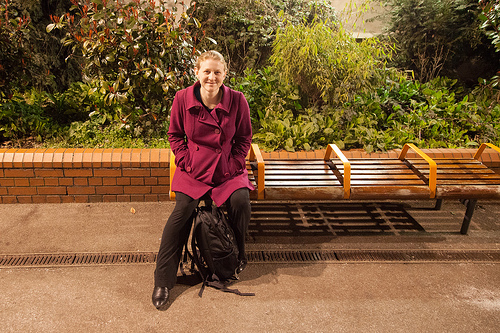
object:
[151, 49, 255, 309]
woman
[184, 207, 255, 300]
backpack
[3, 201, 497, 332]
ground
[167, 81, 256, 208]
jacket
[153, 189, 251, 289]
pants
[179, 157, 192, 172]
pockets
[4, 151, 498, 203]
wall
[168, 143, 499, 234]
bench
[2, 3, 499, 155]
trees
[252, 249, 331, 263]
grate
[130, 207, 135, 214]
leaf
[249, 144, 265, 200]
handle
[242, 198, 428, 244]
shadow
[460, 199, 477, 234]
leg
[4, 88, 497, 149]
vegetation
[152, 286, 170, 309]
shoe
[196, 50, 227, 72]
hair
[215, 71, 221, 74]
eyes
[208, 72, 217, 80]
nose